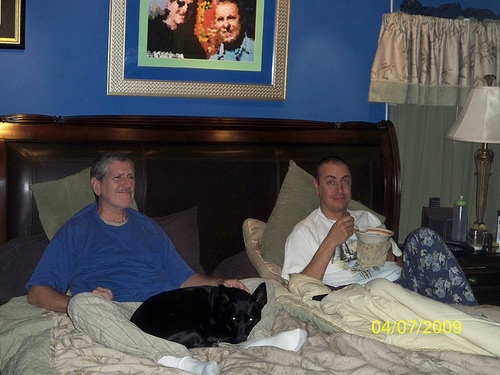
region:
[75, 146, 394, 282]
two men sitting on a bed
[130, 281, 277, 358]
black dog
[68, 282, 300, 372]
black dog laying between a man's legs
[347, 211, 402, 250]
man holding a bowl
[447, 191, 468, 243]
a plastic bottle on a night stand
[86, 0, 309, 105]
a framed picture on a wall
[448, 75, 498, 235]
a lamp on a night table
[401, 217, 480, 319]
man wearing blue pajama with flower pattern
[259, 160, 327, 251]
a green cushion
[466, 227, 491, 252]
a glass on a night stand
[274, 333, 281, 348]
man socks are white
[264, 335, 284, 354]
man socks are white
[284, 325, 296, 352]
man socks are white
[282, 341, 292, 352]
man socks are white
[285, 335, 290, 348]
man socks are white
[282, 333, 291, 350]
man socks are white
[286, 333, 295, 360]
man socks are white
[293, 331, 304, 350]
man socks are white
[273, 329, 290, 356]
man socks are white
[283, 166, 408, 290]
He is wearing a white shirt.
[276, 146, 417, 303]
He is eating.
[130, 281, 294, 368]
The dog is black.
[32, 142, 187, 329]
he is wearing a blue shirt.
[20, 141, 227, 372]
He is wearing tan pants.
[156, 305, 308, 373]
He is wearing white socks.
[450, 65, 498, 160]
The lampshade is white.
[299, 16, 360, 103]
The wall is blue.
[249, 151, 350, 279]
The pillow is tan.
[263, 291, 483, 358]
The comforter is tan.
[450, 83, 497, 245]
a tall lamp with a white shade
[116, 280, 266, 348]
a black dog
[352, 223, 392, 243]
a beige bowl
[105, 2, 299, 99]
part of a picture frame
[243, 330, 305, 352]
a man's white sock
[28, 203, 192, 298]
men's blue short sleeve shirt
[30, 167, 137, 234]
a small green pillow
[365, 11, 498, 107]
a green and beige curtain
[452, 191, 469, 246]
a water bottle with a green top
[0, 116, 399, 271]
a brown headboard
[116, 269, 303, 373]
A dog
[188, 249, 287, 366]
A dog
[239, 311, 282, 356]
A dog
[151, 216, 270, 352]
A dog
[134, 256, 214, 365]
A dog